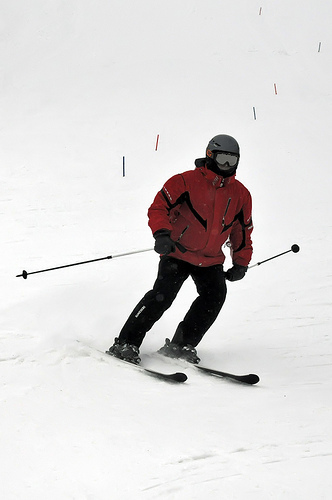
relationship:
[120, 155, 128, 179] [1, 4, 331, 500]
stick in snow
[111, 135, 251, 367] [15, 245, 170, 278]
skier holding pole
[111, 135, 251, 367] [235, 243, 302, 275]
skier holding pole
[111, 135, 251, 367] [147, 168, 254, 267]
skier wearing coat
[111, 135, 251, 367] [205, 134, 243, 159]
skier wearing helmet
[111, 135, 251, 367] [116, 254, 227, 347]
skier wearing pants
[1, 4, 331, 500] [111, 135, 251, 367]
snow beneath skier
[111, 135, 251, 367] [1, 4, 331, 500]
skier skiing in snow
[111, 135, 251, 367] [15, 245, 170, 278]
skier has pole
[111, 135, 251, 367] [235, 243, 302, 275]
skier has pole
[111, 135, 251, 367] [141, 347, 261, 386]
skier has ski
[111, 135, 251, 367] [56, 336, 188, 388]
skier has ski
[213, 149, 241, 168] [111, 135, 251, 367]
goggles on skier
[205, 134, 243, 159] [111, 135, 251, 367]
helmet on skier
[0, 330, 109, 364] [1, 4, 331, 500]
tracks imprinted in snow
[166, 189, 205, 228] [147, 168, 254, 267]
stripe on coat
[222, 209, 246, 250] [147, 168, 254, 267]
stripe on coat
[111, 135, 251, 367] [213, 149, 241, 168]
skier wearing goggles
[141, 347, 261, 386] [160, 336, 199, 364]
ski under boot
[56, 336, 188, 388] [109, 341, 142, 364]
ski under boot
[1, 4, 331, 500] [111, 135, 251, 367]
snow under skier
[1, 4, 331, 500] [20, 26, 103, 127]
snow has part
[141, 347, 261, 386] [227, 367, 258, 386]
ski has part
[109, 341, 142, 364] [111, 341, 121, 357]
boot has part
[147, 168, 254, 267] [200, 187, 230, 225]
coat has part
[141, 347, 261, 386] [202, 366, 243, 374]
ski has edge